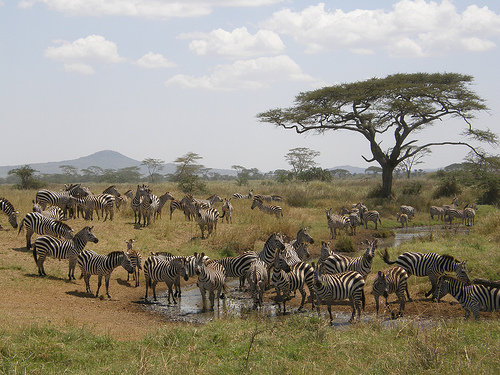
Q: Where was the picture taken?
A: It was taken at the plain.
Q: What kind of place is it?
A: It is a plain.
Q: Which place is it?
A: It is a plain.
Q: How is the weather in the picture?
A: It is cloudy.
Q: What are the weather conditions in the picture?
A: It is cloudy.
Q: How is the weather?
A: It is cloudy.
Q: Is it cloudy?
A: Yes, it is cloudy.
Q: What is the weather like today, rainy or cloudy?
A: It is cloudy.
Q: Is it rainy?
A: No, it is cloudy.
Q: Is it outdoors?
A: Yes, it is outdoors.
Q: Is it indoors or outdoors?
A: It is outdoors.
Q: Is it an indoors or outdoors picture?
A: It is outdoors.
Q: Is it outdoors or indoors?
A: It is outdoors.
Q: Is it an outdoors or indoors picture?
A: It is outdoors.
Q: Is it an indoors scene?
A: No, it is outdoors.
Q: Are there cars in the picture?
A: No, there are no cars.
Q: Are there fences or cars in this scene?
A: No, there are no cars or fences.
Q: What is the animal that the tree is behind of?
A: The animal is a zebra.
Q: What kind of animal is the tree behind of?
A: The tree is behind the zebra.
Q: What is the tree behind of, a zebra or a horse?
A: The tree is behind a zebra.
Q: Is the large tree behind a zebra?
A: Yes, the tree is behind a zebra.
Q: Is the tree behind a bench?
A: No, the tree is behind a zebra.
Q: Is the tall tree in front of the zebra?
A: No, the tree is behind the zebra.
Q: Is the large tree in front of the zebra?
A: No, the tree is behind the zebra.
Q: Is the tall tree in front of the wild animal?
A: No, the tree is behind the zebra.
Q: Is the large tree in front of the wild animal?
A: No, the tree is behind the zebra.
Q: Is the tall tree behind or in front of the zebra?
A: The tree is behind the zebra.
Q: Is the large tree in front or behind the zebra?
A: The tree is behind the zebra.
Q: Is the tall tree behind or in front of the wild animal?
A: The tree is behind the zebra.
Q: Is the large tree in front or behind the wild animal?
A: The tree is behind the zebra.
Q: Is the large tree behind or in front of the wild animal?
A: The tree is behind the zebra.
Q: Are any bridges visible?
A: No, there are no bridges.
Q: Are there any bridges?
A: No, there are no bridges.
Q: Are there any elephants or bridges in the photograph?
A: No, there are no bridges or elephants.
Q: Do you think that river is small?
A: Yes, the river is small.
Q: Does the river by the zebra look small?
A: Yes, the river is small.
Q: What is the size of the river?
A: The river is small.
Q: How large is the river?
A: The river is small.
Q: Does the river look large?
A: No, the river is small.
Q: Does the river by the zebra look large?
A: No, the river is small.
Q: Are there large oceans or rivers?
A: No, there is a river but it is small.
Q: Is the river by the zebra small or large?
A: The river is small.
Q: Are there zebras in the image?
A: Yes, there is a zebra.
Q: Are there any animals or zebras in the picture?
A: Yes, there is a zebra.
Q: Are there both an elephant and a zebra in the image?
A: No, there is a zebra but no elephants.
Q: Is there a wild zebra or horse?
A: Yes, there is a wild zebra.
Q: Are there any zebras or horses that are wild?
A: Yes, the zebra is wild.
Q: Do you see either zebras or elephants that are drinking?
A: Yes, the zebra is drinking.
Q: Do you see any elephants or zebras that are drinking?
A: Yes, the zebra is drinking.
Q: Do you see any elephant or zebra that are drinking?
A: Yes, the zebra is drinking.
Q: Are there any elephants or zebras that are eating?
A: Yes, the zebra is eating.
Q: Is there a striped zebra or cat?
A: Yes, there is a striped zebra.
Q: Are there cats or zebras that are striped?
A: Yes, the zebra is striped.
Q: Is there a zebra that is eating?
A: Yes, there is a zebra that is eating.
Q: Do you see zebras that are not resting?
A: Yes, there is a zebra that is eating .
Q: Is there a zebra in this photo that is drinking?
A: Yes, there is a zebra that is drinking.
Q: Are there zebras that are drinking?
A: Yes, there is a zebra that is drinking.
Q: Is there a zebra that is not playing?
A: Yes, there is a zebra that is drinking.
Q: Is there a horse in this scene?
A: No, there are no horses.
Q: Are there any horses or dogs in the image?
A: No, there are no horses or dogs.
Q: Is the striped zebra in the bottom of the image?
A: Yes, the zebra is in the bottom of the image.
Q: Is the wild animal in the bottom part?
A: Yes, the zebra is in the bottom of the image.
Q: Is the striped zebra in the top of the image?
A: No, the zebra is in the bottom of the image.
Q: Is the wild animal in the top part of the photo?
A: No, the zebra is in the bottom of the image.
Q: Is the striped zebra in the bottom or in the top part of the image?
A: The zebra is in the bottom of the image.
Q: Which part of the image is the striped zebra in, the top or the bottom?
A: The zebra is in the bottom of the image.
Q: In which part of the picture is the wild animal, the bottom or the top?
A: The zebra is in the bottom of the image.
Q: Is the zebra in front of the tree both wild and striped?
A: Yes, the zebra is wild and striped.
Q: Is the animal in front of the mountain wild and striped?
A: Yes, the zebra is wild and striped.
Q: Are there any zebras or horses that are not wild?
A: No, there is a zebra but it is wild.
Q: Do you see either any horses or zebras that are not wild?
A: No, there is a zebra but it is wild.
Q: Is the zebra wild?
A: Yes, the zebra is wild.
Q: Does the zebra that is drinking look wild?
A: Yes, the zebra is wild.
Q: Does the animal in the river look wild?
A: Yes, the zebra is wild.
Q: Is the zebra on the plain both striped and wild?
A: Yes, the zebra is striped and wild.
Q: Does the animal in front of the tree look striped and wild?
A: Yes, the zebra is striped and wild.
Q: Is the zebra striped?
A: Yes, the zebra is striped.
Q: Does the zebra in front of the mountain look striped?
A: Yes, the zebra is striped.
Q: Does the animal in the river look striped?
A: Yes, the zebra is striped.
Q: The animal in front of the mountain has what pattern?
A: The zebra is striped.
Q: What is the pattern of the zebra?
A: The zebra is striped.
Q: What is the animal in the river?
A: The animal is a zebra.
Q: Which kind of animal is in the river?
A: The animal is a zebra.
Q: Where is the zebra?
A: The zebra is in the river.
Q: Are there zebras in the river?
A: Yes, there is a zebra in the river.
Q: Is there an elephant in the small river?
A: No, there is a zebra in the river.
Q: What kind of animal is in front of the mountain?
A: The animal is a zebra.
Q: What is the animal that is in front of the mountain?
A: The animal is a zebra.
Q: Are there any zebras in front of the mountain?
A: Yes, there is a zebra in front of the mountain.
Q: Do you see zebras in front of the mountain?
A: Yes, there is a zebra in front of the mountain.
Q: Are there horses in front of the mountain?
A: No, there is a zebra in front of the mountain.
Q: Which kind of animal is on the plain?
A: The animal is a zebra.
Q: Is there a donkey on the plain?
A: No, there is a zebra on the plain.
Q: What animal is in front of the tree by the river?
A: The zebra is in front of the tree.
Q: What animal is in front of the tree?
A: The zebra is in front of the tree.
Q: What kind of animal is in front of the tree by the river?
A: The animal is a zebra.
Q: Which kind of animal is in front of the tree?
A: The animal is a zebra.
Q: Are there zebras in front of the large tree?
A: Yes, there is a zebra in front of the tree.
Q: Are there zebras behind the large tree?
A: No, the zebra is in front of the tree.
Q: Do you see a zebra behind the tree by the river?
A: No, the zebra is in front of the tree.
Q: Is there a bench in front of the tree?
A: No, there is a zebra in front of the tree.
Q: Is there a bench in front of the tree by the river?
A: No, there is a zebra in front of the tree.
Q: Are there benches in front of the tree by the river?
A: No, there is a zebra in front of the tree.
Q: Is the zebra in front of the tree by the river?
A: Yes, the zebra is in front of the tree.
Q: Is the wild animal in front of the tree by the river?
A: Yes, the zebra is in front of the tree.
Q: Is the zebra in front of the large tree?
A: Yes, the zebra is in front of the tree.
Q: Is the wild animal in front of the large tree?
A: Yes, the zebra is in front of the tree.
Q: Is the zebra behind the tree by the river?
A: No, the zebra is in front of the tree.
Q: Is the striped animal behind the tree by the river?
A: No, the zebra is in front of the tree.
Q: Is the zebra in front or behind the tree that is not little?
A: The zebra is in front of the tree.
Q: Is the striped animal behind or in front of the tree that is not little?
A: The zebra is in front of the tree.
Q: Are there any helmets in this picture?
A: No, there are no helmets.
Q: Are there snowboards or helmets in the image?
A: No, there are no helmets or snowboards.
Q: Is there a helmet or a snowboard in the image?
A: No, there are no helmets or snowboards.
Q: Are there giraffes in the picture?
A: No, there are no giraffes.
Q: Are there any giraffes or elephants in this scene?
A: No, there are no giraffes or elephants.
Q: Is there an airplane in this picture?
A: No, there are no airplanes.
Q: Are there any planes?
A: No, there are no planes.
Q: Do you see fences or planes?
A: No, there are no planes or fences.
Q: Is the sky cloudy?
A: Yes, the sky is cloudy.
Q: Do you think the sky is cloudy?
A: Yes, the sky is cloudy.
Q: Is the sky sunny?
A: No, the sky is cloudy.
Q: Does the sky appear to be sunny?
A: No, the sky is cloudy.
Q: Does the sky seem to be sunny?
A: No, the sky is cloudy.